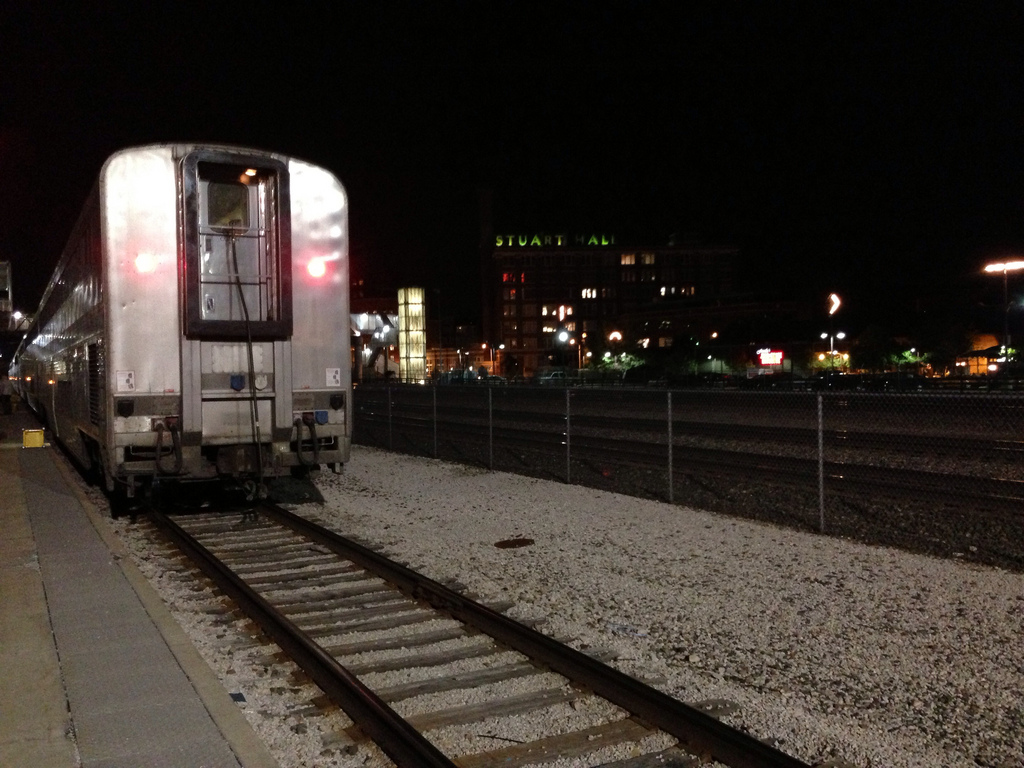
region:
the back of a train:
[36, 112, 378, 501]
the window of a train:
[179, 143, 287, 322]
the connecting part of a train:
[148, 434, 305, 499]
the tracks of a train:
[192, 499, 579, 765]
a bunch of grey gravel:
[548, 512, 727, 636]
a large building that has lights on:
[488, 202, 685, 359]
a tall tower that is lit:
[365, 281, 441, 373]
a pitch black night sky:
[597, 133, 791, 211]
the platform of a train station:
[17, 544, 174, 764]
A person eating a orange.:
[408, 438, 570, 575]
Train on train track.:
[95, 130, 383, 513]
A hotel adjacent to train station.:
[477, 221, 738, 383]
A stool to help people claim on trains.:
[8, 417, 53, 456]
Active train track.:
[171, 497, 753, 761]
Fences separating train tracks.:
[423, 357, 1016, 517]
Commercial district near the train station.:
[398, 218, 1021, 384]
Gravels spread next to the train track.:
[578, 535, 1022, 665]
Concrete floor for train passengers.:
[5, 506, 126, 766]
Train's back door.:
[177, 139, 304, 485]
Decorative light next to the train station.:
[397, 282, 430, 391]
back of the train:
[40, 117, 442, 547]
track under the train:
[148, 493, 504, 757]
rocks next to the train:
[515, 487, 681, 627]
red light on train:
[110, 234, 193, 302]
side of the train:
[0, 228, 149, 445]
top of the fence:
[448, 345, 891, 437]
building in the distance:
[442, 202, 740, 357]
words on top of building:
[455, 196, 677, 269]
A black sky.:
[1, 2, 1022, 375]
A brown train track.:
[155, 488, 808, 765]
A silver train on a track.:
[4, 138, 350, 511]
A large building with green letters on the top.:
[487, 231, 740, 383]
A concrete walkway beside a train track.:
[4, 390, 270, 765]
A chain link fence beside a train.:
[351, 381, 1022, 568]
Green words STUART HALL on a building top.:
[490, 233, 620, 250]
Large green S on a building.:
[491, 231, 505, 250]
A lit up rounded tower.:
[393, 285, 426, 385]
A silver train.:
[7, 140, 353, 515]